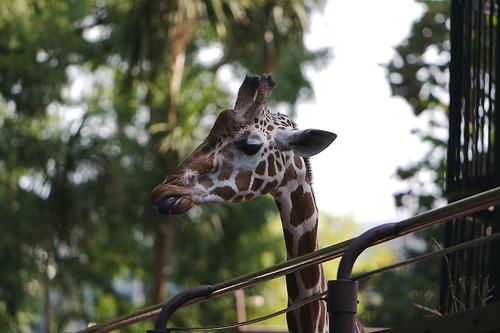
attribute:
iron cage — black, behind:
[439, 2, 499, 319]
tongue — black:
[140, 180, 197, 233]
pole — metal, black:
[318, 232, 365, 328]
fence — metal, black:
[256, 240, 488, 293]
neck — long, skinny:
[256, 178, 348, 315]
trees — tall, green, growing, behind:
[1, 0, 336, 332]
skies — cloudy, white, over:
[268, 1, 498, 226]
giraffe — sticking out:
[142, 43, 337, 331]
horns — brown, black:
[233, 74, 273, 111]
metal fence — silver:
[67, 181, 495, 331]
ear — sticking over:
[273, 126, 338, 158]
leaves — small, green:
[382, 41, 433, 121]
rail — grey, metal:
[401, 175, 498, 236]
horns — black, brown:
[214, 73, 294, 117]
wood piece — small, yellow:
[233, 287, 282, 332]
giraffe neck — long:
[277, 182, 329, 329]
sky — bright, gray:
[292, 1, 450, 259]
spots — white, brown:
[286, 179, 324, 234]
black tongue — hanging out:
[140, 178, 198, 230]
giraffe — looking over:
[148, 70, 368, 331]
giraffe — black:
[145, 68, 338, 331]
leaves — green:
[386, 3, 447, 115]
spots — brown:
[213, 160, 280, 205]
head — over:
[144, 69, 334, 220]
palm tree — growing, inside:
[78, 7, 297, 292]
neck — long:
[271, 140, 332, 330]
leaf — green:
[33, 104, 138, 233]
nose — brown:
[135, 171, 180, 205]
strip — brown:
[166, 131, 222, 183]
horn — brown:
[208, 62, 272, 99]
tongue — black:
[156, 198, 199, 235]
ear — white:
[289, 115, 343, 156]